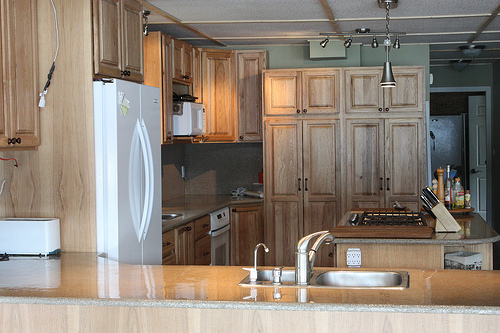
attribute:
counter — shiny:
[2, 237, 498, 312]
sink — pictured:
[237, 226, 409, 292]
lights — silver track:
[317, 30, 406, 52]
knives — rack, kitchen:
[418, 185, 463, 235]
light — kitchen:
[379, 0, 396, 91]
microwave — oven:
[185, 94, 207, 129]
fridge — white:
[91, 74, 169, 266]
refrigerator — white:
[87, 66, 175, 271]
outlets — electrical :
[343, 245, 363, 270]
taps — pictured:
[225, 227, 347, 302]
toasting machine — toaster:
[0, 209, 65, 268]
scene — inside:
[7, 2, 498, 329]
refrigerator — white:
[78, 29, 242, 310]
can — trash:
[441, 247, 493, 274]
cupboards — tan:
[268, 121, 417, 200]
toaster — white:
[6, 209, 63, 254]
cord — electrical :
[25, 29, 82, 115]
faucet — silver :
[233, 197, 408, 299]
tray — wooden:
[435, 200, 477, 212]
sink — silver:
[238, 223, 423, 298]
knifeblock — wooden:
[430, 199, 466, 236]